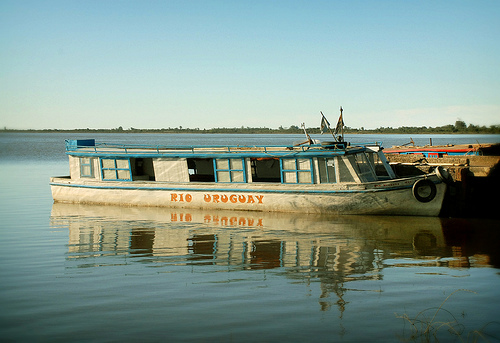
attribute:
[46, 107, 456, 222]
boat — white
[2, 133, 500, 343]
water — calm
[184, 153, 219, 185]
window — open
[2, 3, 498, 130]
sky — blue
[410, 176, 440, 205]
life preserver — round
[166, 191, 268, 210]
writing — orange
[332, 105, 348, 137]
flag — small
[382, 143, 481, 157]
roof — red